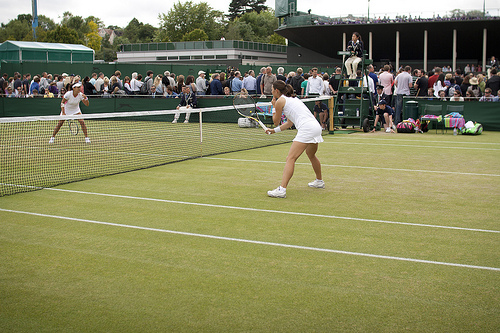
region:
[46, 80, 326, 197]
two tennis players on the court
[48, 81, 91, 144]
tennis player with a hat on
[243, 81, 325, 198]
tennis player without a hat on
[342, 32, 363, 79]
judge watching the tennis players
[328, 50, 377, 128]
green ladder with a woman on it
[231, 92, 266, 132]
black and white racket in the woman's hand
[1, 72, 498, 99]
people behind the road watching the game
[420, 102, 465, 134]
green chairs against the wall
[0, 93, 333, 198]
black and white net on the court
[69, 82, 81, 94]
white hat on the tennis player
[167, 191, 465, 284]
white lines on the tennis court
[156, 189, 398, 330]
tennis court is a lime green color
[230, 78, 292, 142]
player holding the tennis racket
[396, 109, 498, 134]
bags on the side of the court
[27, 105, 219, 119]
top of tennis net is white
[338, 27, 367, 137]
judge sitting on the high chair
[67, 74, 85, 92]
player is wearing a visor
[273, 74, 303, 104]
woman has a pony tail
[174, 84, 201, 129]
man sitting in a chair next to court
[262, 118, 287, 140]
wrist band is white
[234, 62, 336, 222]
A woman with a tennis racket.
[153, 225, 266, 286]
The green grass and white lines of the court.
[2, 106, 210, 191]
A large tennis net.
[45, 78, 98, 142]
A woman holding her tennis racket to the ground.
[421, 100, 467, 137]
Two chairs with towels draped over them.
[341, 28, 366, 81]
A referee sits, watching the game.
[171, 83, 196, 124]
A man sitting to the side of the court.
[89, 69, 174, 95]
People milling about in the stands.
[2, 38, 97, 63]
A large, green building.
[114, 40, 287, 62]
A white building with green trim.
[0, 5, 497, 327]
A women's tennis match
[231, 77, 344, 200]
A woman's tennis player readies herself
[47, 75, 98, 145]
A woman readies herself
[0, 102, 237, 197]
A tennis net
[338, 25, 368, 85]
The judge watches keenly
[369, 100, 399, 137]
Ball shagger readies themself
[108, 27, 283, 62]
The top of what is presumably an athletics buildign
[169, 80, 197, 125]
A second judge watches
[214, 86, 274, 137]
A woman holds her tennis racket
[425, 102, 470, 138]
two chairs for the competitors and their coaches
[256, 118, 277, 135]
she is holding the racket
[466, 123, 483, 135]
the bag is green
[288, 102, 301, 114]
the shirt is white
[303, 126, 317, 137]
the skirt is white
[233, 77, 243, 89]
the shirt is blue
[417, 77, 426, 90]
the shirt is black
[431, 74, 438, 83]
the shirt is red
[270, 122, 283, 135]
she is wearing a wrist band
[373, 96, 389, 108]
the hat is blue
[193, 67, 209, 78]
the hat is white